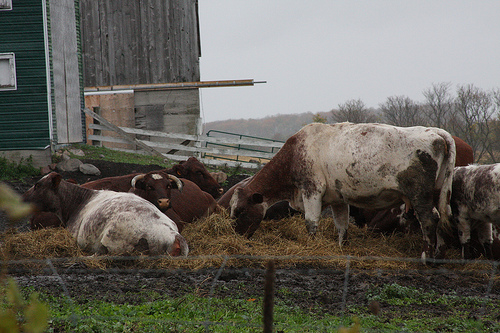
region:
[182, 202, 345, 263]
Hay on the ground.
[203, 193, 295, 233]
A cow eating hay.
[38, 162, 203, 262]
Cows lying on the ground.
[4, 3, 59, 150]
Part of the barn is green.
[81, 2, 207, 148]
The barn is wooden.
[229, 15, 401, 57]
The sky is grey.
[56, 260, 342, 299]
The ground is mostly mud.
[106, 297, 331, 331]
The grass is green.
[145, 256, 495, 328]
The fence is wire.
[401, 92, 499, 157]
Trees in the background.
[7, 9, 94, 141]
green door on a barn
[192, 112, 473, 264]
brown and white cow eating straw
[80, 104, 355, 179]
white fence keeping cows in the pasture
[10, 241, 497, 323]
wire fencing to stop cows from getting away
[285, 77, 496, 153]
bare trees in the distance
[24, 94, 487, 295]
herd of cattle by a barn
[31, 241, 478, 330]
muddy ground between grass and hay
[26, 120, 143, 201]
pile of rocks in front of barn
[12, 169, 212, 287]
two cows lying together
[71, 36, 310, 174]
long sharp object extending away from the barn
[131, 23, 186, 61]
this is gray barn siding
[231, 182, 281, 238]
thid is a cows head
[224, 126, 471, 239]
this is a cow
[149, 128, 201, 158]
this is a slat fence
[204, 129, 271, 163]
this is a metal gate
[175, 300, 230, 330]
this is green grass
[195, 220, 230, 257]
this is hay for cow food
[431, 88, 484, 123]
these are tress with no leaves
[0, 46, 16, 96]
this is a window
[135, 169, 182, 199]
this cow has horns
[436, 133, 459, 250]
a tail of a cow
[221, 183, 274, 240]
a cow eating hay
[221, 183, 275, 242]
a head of a cow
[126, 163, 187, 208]
a head of a cow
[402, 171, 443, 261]
the hind leg of a cow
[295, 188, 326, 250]
the front leg of a cow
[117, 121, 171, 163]
a white wooden fence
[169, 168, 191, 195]
a horn of a cow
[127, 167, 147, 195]
a horn of a cow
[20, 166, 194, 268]
two laying down cows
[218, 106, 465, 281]
large brown and white eating cow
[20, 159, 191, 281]
brown and white cow looking left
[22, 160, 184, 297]
white and brown cow sitting down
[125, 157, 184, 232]
face of brown cow with horns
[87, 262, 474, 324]
muddy grassy cow pen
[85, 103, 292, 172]
white wooden fence enclosure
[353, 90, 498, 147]
leafless gray hardwood tree branches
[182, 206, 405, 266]
dry yellow hay for cow food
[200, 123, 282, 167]
green metal cattle fence gate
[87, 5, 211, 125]
large gray wooden barn